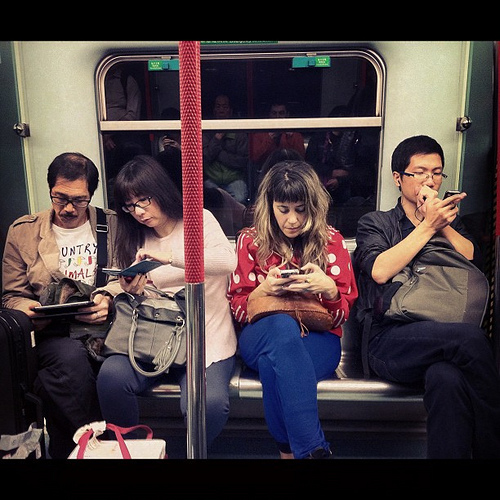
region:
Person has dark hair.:
[383, 133, 457, 170]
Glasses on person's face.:
[400, 170, 489, 195]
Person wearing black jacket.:
[361, 213, 391, 236]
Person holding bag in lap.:
[400, 264, 450, 315]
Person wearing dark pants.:
[399, 325, 465, 401]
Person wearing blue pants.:
[264, 350, 311, 387]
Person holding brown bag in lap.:
[263, 290, 326, 329]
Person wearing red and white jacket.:
[238, 232, 349, 305]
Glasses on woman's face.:
[123, 191, 171, 232]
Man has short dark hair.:
[41, 155, 116, 167]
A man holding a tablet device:
[3, 150, 112, 427]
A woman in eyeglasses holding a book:
[98, 160, 233, 441]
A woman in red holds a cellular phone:
[230, 163, 360, 461]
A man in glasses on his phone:
[354, 135, 499, 462]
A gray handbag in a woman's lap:
[102, 288, 194, 375]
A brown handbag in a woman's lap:
[243, 288, 333, 333]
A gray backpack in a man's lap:
[373, 240, 488, 327]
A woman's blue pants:
[238, 317, 340, 457]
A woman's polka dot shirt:
[235, 223, 355, 330]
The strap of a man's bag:
[91, 204, 107, 291]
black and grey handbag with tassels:
[102, 284, 187, 377]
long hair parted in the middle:
[249, 157, 331, 274]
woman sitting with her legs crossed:
[223, 158, 360, 460]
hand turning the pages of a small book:
[99, 247, 169, 280]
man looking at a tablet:
[3, 149, 128, 386]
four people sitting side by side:
[0, 133, 499, 468]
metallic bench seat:
[150, 375, 422, 402]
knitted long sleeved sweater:
[128, 209, 238, 371]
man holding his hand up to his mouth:
[353, 132, 498, 481]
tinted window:
[91, 41, 390, 253]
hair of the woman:
[247, 175, 330, 218]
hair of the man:
[377, 125, 440, 150]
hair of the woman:
[120, 155, 170, 188]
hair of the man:
[52, 149, 85, 180]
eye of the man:
[415, 162, 428, 176]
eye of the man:
[427, 165, 448, 174]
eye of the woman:
[297, 203, 307, 218]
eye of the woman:
[278, 208, 290, 217]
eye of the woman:
[145, 198, 153, 207]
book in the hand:
[99, 263, 135, 281]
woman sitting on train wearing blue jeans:
[223, 158, 353, 464]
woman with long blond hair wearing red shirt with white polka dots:
[226, 154, 367, 454]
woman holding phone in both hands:
[277, 266, 302, 288]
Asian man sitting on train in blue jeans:
[344, 133, 488, 490]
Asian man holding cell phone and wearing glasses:
[346, 130, 498, 493]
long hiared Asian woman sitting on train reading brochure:
[85, 152, 237, 453]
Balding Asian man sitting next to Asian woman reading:
[5, 141, 131, 448]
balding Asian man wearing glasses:
[48, 190, 93, 210]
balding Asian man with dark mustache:
[57, 210, 82, 216]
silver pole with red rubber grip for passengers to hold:
[177, 38, 212, 454]